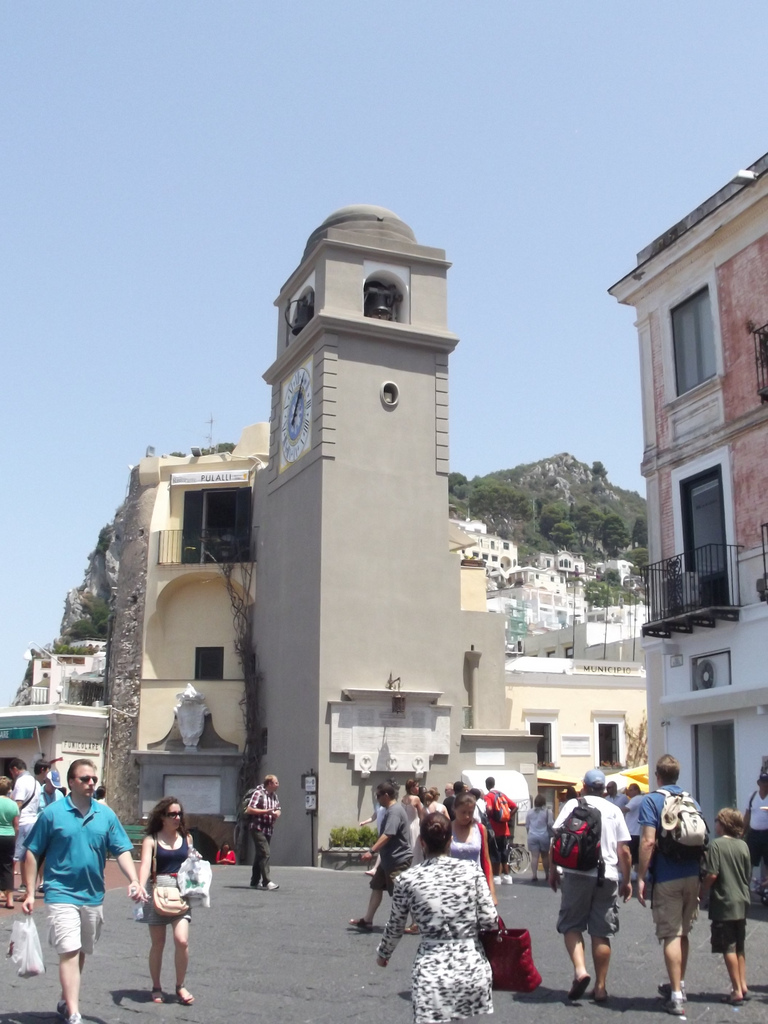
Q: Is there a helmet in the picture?
A: No, there are no helmets.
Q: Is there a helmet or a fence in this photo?
A: No, there are no helmets or fences.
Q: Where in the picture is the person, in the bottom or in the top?
A: The person is in the bottom of the image.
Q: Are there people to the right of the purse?
A: Yes, there is a person to the right of the purse.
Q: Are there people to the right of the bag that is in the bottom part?
A: Yes, there is a person to the right of the purse.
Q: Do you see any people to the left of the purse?
A: No, the person is to the right of the purse.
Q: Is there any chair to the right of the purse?
A: No, there is a person to the right of the purse.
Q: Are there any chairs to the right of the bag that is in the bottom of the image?
A: No, there is a person to the right of the purse.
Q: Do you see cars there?
A: No, there are no cars.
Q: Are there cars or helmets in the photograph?
A: No, there are no cars or helmets.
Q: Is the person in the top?
A: No, the person is in the bottom of the image.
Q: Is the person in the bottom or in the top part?
A: The person is in the bottom of the image.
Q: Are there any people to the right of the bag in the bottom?
A: Yes, there is a person to the right of the purse.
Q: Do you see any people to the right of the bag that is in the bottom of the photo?
A: Yes, there is a person to the right of the purse.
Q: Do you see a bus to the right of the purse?
A: No, there is a person to the right of the purse.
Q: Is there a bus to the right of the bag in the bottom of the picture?
A: No, there is a person to the right of the purse.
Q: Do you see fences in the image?
A: No, there are no fences.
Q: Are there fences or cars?
A: No, there are no fences or cars.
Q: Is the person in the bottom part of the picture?
A: Yes, the person is in the bottom of the image.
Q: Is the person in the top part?
A: No, the person is in the bottom of the image.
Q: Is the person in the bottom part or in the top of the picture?
A: The person is in the bottom of the image.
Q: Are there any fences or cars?
A: No, there are no fences or cars.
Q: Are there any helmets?
A: No, there are no helmets.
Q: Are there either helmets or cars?
A: No, there are no helmets or cars.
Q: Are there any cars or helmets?
A: No, there are no helmets or cars.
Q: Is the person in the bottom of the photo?
A: Yes, the person is in the bottom of the image.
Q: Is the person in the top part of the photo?
A: No, the person is in the bottom of the image.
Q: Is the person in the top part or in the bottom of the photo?
A: The person is in the bottom of the image.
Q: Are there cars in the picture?
A: No, there are no cars.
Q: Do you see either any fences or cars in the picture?
A: No, there are no cars or fences.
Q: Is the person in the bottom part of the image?
A: Yes, the person is in the bottom of the image.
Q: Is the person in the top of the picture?
A: No, the person is in the bottom of the image.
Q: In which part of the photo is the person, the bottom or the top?
A: The person is in the bottom of the image.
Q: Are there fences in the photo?
A: No, there are no fences.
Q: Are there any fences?
A: No, there are no fences.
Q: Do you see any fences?
A: No, there are no fences.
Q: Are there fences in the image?
A: No, there are no fences.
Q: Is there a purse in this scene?
A: Yes, there is a purse.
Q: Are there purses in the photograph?
A: Yes, there is a purse.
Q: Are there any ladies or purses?
A: Yes, there is a purse.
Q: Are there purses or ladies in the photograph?
A: Yes, there is a purse.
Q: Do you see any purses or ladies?
A: Yes, there is a purse.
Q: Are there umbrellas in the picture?
A: No, there are no umbrellas.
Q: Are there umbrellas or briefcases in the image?
A: No, there are no umbrellas or briefcases.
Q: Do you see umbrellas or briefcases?
A: No, there are no umbrellas or briefcases.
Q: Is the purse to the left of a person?
A: Yes, the purse is to the left of a person.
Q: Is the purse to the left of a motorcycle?
A: No, the purse is to the left of a person.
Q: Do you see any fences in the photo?
A: No, there are no fences.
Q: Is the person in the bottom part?
A: Yes, the person is in the bottom of the image.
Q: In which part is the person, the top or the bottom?
A: The person is in the bottom of the image.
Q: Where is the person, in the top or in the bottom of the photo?
A: The person is in the bottom of the image.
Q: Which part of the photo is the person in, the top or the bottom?
A: The person is in the bottom of the image.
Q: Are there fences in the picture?
A: No, there are no fences.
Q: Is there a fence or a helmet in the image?
A: No, there are no fences or helmets.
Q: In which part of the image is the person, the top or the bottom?
A: The person is in the bottom of the image.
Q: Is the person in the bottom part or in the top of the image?
A: The person is in the bottom of the image.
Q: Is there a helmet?
A: No, there are no helmets.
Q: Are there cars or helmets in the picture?
A: No, there are no helmets or cars.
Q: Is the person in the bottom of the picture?
A: Yes, the person is in the bottom of the image.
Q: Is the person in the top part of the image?
A: No, the person is in the bottom of the image.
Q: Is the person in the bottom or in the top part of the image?
A: The person is in the bottom of the image.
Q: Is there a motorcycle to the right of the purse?
A: No, there is a person to the right of the purse.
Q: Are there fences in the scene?
A: No, there are no fences.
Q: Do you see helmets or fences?
A: No, there are no fences or helmets.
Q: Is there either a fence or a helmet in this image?
A: No, there are no fences or helmets.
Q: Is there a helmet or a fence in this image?
A: No, there are no fences or helmets.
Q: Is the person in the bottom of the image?
A: Yes, the person is in the bottom of the image.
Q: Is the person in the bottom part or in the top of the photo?
A: The person is in the bottom of the image.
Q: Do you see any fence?
A: No, there are no fences.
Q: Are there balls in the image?
A: No, there are no balls.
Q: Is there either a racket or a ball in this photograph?
A: No, there are no balls or rackets.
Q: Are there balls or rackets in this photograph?
A: No, there are no balls or rackets.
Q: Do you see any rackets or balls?
A: No, there are no balls or rackets.